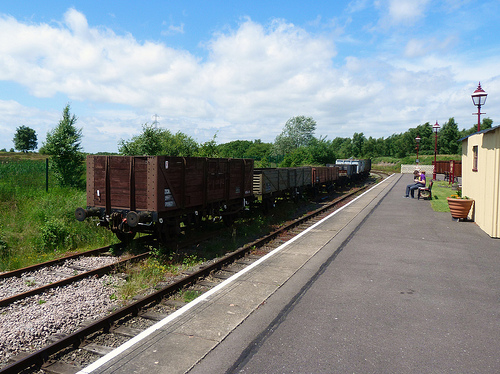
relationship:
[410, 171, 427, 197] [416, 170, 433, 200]
person on bench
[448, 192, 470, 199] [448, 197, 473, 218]
flowers in flower pot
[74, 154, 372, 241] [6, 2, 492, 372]
carriages parked outside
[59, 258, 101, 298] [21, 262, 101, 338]
part of railroad tracks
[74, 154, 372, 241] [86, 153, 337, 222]
carriages has carriages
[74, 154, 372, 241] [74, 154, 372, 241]
carriages on carriages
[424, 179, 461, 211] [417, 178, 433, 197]
grass behind bench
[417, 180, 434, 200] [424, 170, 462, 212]
bench near grass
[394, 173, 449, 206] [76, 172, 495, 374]
bench on concrete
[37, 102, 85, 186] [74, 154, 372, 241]
tree behind carriages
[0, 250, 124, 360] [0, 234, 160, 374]
gravel underneath and next to railroad tracks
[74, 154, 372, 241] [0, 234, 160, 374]
carriages on railroad tracks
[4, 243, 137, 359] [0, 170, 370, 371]
gravel on rail